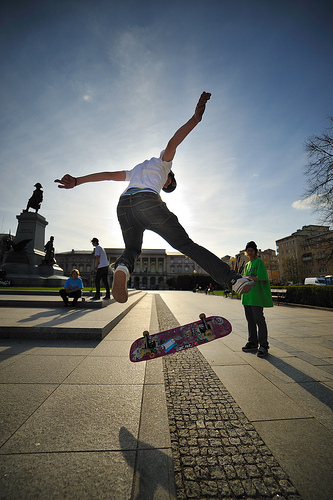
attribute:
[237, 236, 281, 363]
boy — standing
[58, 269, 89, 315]
boy — sitting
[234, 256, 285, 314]
shirt — green, oversized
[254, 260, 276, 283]
sleeve — short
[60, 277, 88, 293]
shirt — blue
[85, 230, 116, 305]
boy — standing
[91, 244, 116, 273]
shirt — white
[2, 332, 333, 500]
ground — paved, dry